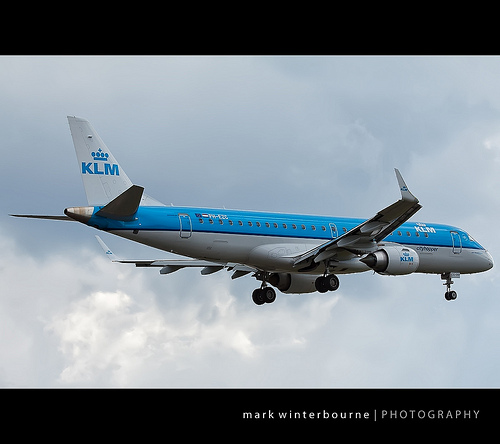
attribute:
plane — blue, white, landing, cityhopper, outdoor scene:
[7, 113, 497, 310]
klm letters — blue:
[79, 159, 122, 179]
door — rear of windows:
[174, 210, 194, 243]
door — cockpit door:
[450, 228, 466, 257]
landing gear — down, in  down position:
[248, 263, 463, 309]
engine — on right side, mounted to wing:
[360, 242, 420, 278]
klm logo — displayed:
[397, 254, 420, 263]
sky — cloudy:
[1, 55, 499, 388]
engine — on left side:
[261, 269, 328, 296]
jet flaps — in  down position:
[97, 164, 422, 280]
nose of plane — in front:
[456, 221, 499, 280]